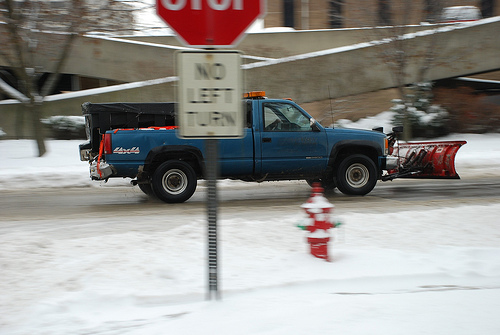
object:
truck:
[78, 91, 469, 204]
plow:
[382, 140, 467, 181]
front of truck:
[286, 99, 397, 197]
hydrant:
[296, 181, 343, 263]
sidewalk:
[18, 266, 497, 334]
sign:
[153, 1, 258, 47]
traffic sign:
[174, 48, 245, 140]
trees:
[331, 2, 455, 142]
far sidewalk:
[1, 169, 87, 192]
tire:
[333, 152, 378, 196]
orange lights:
[244, 90, 264, 99]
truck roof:
[239, 98, 296, 107]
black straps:
[109, 112, 111, 130]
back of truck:
[78, 101, 177, 204]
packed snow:
[1, 209, 500, 298]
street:
[1, 169, 498, 227]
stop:
[159, 0, 245, 11]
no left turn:
[184, 62, 238, 126]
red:
[313, 249, 325, 254]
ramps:
[105, 19, 500, 59]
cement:
[240, 25, 454, 93]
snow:
[340, 110, 397, 132]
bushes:
[388, 95, 452, 138]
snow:
[22, 78, 174, 103]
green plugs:
[295, 222, 344, 232]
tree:
[1, 2, 136, 157]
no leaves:
[96, 3, 126, 23]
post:
[206, 137, 219, 301]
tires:
[150, 157, 198, 205]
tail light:
[102, 133, 113, 154]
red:
[188, 13, 235, 37]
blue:
[231, 140, 319, 173]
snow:
[1, 137, 498, 335]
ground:
[0, 129, 499, 335]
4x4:
[113, 146, 141, 155]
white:
[180, 55, 195, 84]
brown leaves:
[40, 1, 60, 20]